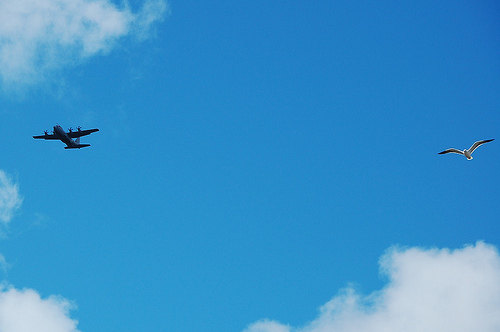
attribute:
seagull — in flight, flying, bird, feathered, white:
[435, 135, 497, 166]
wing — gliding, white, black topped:
[440, 147, 464, 160]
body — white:
[461, 148, 474, 162]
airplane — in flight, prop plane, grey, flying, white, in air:
[30, 118, 103, 152]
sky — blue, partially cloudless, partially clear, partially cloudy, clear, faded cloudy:
[3, 3, 495, 330]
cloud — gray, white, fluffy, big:
[237, 238, 494, 331]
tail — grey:
[63, 137, 88, 149]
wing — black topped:
[469, 138, 494, 156]